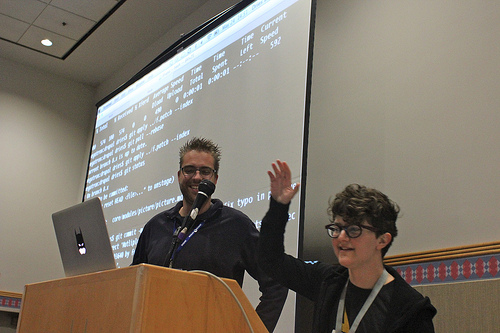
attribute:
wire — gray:
[228, 287, 253, 327]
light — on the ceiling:
[40, 35, 54, 47]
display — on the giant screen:
[73, 2, 305, 332]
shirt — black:
[131, 201, 294, 331]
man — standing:
[129, 137, 289, 332]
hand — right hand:
[260, 159, 300, 208]